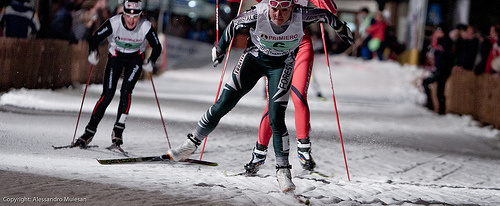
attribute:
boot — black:
[73, 125, 95, 145]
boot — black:
[110, 123, 125, 152]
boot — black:
[165, 132, 202, 165]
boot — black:
[242, 143, 271, 175]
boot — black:
[268, 159, 306, 201]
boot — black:
[292, 138, 325, 173]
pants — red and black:
[249, 36, 310, 157]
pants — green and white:
[193, 45, 296, 163]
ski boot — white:
[165, 135, 203, 165]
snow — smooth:
[2, 31, 499, 203]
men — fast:
[74, 8, 386, 195]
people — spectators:
[423, 21, 498, 81]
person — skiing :
[173, 1, 360, 196]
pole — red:
[316, 20, 352, 181]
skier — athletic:
[243, 0, 338, 173]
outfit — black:
[71, 16, 170, 146]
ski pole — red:
[148, 67, 178, 153]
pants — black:
[191, 52, 306, 157]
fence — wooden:
[388, 37, 472, 84]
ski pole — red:
[316, 19, 351, 180]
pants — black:
[76, 47, 143, 167]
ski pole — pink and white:
[318, 19, 352, 184]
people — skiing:
[53, 6, 353, 188]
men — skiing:
[46, 0, 371, 195]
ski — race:
[97, 156, 218, 166]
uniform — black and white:
[88, 11, 161, 136]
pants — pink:
[253, 40, 318, 141]